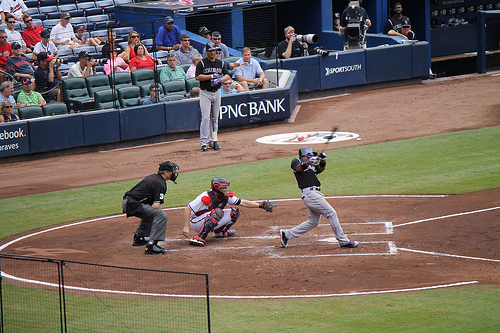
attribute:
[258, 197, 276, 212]
glove — black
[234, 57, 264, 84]
shirt — blue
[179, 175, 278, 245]
catcher — crouched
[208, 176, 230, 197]
head gear — black, red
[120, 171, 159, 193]
shirt — black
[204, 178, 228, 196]
head gear — black, red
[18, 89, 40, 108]
shirt — green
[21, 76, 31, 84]
hat — black, red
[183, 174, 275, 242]
catcher — sitting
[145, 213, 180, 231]
pants — gray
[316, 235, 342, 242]
base — white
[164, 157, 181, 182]
head gear — black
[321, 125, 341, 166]
bat — black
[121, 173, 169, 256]
clothes — black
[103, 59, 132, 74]
top — pink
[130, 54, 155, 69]
top — orange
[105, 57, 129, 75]
shirt — pink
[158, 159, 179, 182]
head gear — black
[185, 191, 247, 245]
uniform — baseball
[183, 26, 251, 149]
player — baseball